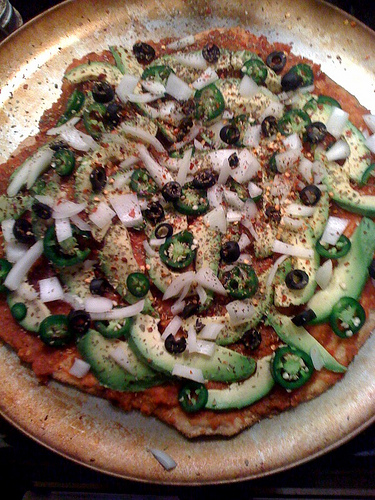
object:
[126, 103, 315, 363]
topping`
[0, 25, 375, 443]
pizza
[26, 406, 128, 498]
crust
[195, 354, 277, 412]
avocado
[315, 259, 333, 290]
onion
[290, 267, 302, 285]
olive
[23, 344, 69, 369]
chili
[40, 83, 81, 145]
sauce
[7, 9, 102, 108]
plate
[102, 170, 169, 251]
pepper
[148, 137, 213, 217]
seasoning